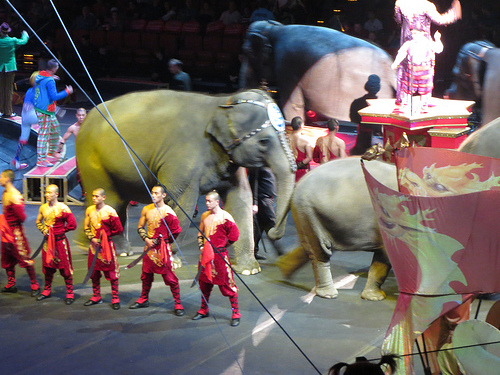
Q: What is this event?
A: A circus.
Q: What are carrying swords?
A: Jugglers.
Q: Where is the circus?
A: In an arena or tent.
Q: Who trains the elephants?
A: Handlers.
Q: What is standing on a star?
A: A clown.